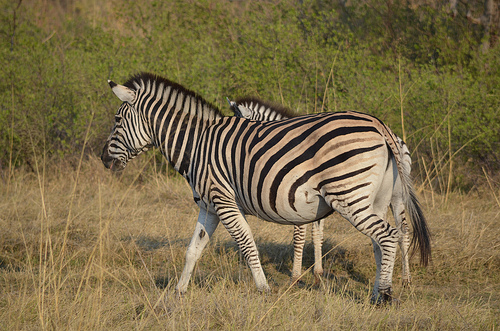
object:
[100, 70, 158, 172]
head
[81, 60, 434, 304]
zebra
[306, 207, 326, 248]
ground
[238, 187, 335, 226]
stomach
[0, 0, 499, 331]
scene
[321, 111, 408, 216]
ass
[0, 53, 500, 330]
grass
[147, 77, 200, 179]
neck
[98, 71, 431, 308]
zebra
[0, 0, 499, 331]
field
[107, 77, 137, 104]
ear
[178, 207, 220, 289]
front leg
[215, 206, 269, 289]
front leg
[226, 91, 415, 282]
baby zebra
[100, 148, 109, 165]
nose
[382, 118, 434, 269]
tail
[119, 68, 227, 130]
mane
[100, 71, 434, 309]
animal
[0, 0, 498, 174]
bushes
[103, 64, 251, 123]
mohawk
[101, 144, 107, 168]
black nose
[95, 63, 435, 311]
body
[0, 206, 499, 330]
foreground